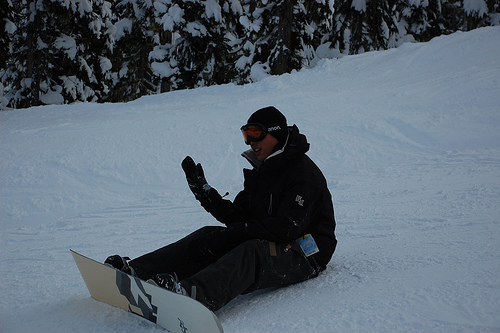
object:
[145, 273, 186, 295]
boots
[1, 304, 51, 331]
snow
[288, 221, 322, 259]
station tag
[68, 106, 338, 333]
snowboarding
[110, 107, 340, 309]
gear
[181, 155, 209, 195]
gloves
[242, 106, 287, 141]
hat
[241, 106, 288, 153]
head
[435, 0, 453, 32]
trees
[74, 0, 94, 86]
bush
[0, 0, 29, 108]
branches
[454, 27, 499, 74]
snow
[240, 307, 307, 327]
snow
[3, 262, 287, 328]
ground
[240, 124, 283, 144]
goggles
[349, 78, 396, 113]
snow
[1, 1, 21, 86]
snow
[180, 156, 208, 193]
hand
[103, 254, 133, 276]
boots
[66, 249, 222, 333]
snowboard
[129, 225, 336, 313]
snowsuit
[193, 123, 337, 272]
coat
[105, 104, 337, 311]
body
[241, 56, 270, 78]
trees snow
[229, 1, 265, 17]
trees snow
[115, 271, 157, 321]
design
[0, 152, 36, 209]
snow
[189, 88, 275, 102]
snow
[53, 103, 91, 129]
snow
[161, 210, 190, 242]
snow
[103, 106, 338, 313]
guy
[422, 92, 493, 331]
ground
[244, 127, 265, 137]
lens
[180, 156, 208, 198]
mitten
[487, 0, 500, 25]
tree limbs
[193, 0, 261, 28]
snow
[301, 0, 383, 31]
trees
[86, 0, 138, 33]
snow